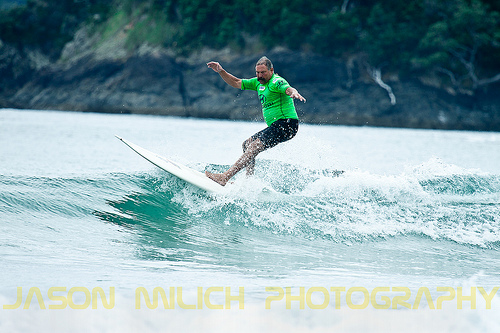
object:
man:
[203, 54, 307, 188]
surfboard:
[110, 133, 227, 201]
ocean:
[6, 123, 499, 315]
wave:
[15, 171, 494, 224]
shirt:
[239, 74, 300, 126]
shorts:
[248, 118, 301, 149]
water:
[329, 136, 427, 199]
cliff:
[17, 37, 498, 125]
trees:
[8, 2, 495, 63]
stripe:
[276, 94, 288, 120]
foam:
[218, 173, 496, 249]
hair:
[255, 55, 275, 70]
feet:
[202, 169, 230, 187]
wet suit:
[236, 72, 299, 150]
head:
[255, 58, 275, 83]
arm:
[220, 69, 256, 92]